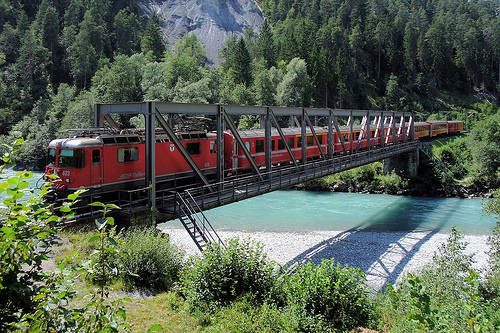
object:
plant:
[84, 221, 187, 294]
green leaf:
[86, 201, 105, 207]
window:
[184, 142, 202, 157]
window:
[115, 146, 140, 163]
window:
[252, 139, 266, 153]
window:
[276, 138, 285, 152]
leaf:
[105, 202, 122, 209]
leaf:
[17, 180, 30, 193]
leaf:
[97, 217, 109, 230]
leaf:
[105, 216, 116, 228]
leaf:
[65, 192, 79, 202]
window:
[58, 147, 84, 170]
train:
[36, 119, 466, 196]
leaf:
[366, 17, 394, 46]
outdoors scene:
[0, 0, 499, 332]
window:
[91, 147, 101, 166]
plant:
[463, 108, 499, 177]